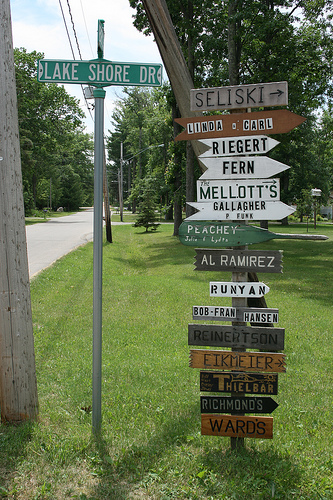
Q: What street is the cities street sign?
A: Lake Shore Dr.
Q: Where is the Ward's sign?
A: Last sign at the bottom.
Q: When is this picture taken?
A: Day time.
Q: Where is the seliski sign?
A: First sign at the top.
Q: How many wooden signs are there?
A: Fifteen.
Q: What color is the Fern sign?
A: White.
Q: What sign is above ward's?
A: Richmond's.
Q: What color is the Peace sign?
A: Green.